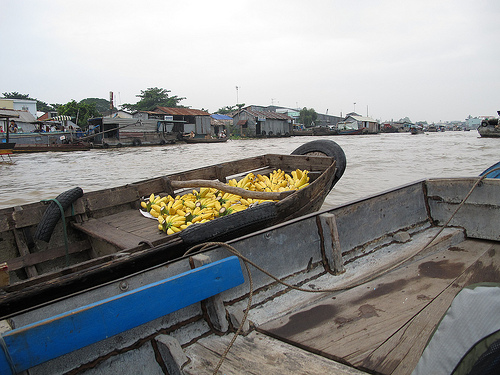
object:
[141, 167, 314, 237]
bananas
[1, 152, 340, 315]
boat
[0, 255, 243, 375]
plank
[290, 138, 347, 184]
tire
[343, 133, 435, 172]
water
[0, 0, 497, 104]
sky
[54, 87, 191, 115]
trees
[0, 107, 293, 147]
houses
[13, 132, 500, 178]
river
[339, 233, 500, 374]
deck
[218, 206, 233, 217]
tops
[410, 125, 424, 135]
boat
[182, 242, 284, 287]
wires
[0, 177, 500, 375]
boat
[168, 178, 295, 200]
pole